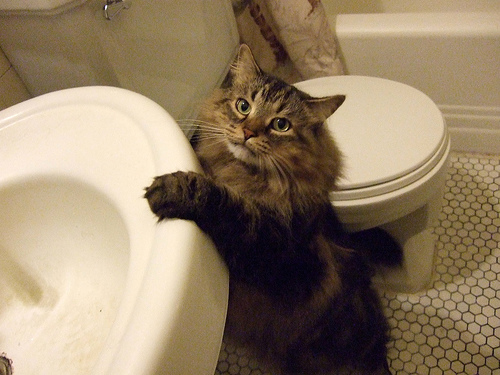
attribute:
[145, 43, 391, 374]
cat — brown, tabby, grey, standing, fluffy, black, looking at camera, striped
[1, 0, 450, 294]
toilet — white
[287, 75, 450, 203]
seat — white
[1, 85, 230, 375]
sink — white, round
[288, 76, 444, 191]
cover — white, closed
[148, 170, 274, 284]
paw — dark brown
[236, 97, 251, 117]
eye — green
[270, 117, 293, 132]
eye — green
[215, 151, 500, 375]
tile — white, hexagonal, brown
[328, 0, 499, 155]
bathtub — white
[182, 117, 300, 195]
whiskers — long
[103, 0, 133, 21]
flush handle — metal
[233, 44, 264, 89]
ear — brown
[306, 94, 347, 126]
ear — brown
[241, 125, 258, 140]
nose — dark brown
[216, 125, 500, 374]
floor — white, tiled, black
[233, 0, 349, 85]
shower curtain — patterned, brown, white